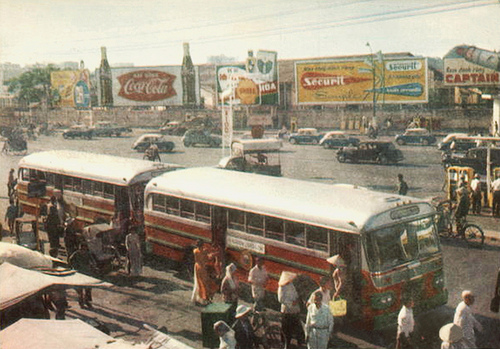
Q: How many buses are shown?
A: Two.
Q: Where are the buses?
A: On the street.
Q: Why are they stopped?
A: To allow passengers to enter and exit.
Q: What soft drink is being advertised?
A: Coca Cola.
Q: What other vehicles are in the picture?
A: Bicycles, cars, and rickshaws.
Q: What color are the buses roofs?
A: White.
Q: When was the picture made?
A: Daytime.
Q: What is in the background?
A: Billboards.